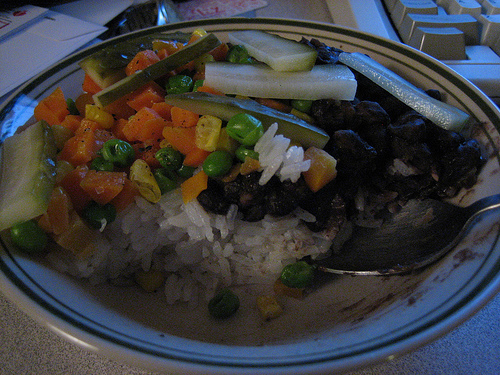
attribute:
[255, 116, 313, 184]
rice — sticky, white, small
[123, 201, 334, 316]
rice — white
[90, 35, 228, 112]
pickle — spear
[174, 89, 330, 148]
pickle — spear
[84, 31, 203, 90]
pickle — spear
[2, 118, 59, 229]
pickle — spear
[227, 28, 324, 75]
pickle — spear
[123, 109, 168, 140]
carrot — small piece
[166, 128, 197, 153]
carrot — small piece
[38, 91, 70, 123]
carrot — small piece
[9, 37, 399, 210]
vegetables — mixed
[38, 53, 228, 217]
carrots — cut up, small, diced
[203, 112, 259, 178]
peas — green, fresh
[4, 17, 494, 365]
dish — rimmed, green, green trim, black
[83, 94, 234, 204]
corn — small pieces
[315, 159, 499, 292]
spoon — silver, covered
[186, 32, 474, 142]
beans — green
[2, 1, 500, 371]
counter — white, speckled, gray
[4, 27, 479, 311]
food — vegetarian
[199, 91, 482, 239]
beans — black